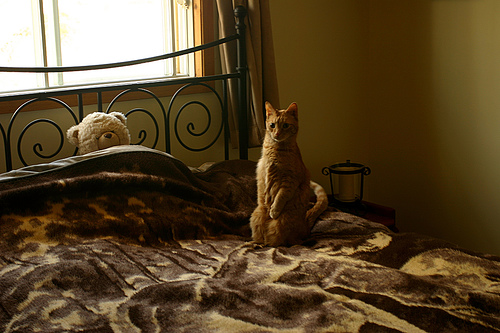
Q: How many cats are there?
A: One.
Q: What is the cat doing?
A: Standing on its hind legs.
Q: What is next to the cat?
A: Teddy bear.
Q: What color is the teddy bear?
A: White.